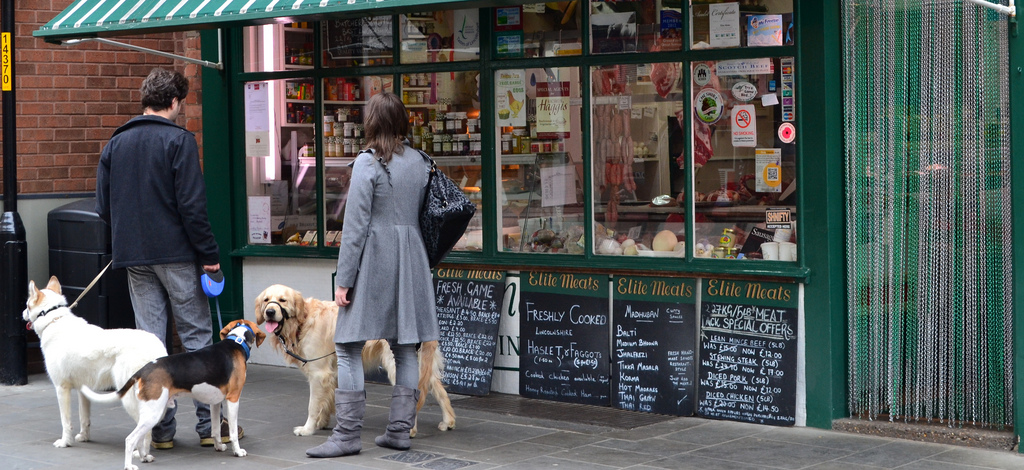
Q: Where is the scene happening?
A: Outside a bakery.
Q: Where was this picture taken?
A: Outside a shop.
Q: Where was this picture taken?
A: In front of cafe.